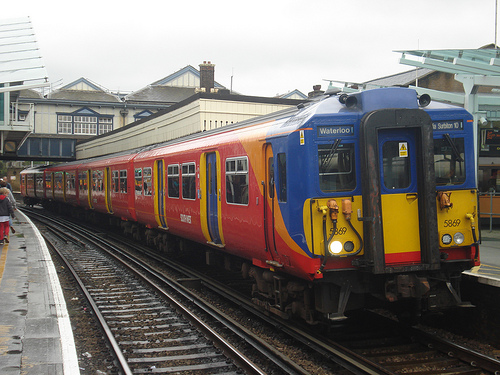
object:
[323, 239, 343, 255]
headlight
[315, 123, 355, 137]
sign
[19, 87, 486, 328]
train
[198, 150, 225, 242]
door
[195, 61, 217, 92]
chimney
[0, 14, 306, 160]
building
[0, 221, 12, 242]
pants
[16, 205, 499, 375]
tracks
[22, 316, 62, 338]
bricks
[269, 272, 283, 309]
ladder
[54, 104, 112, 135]
window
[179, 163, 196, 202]
windows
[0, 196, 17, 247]
people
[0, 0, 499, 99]
sky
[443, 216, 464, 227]
train number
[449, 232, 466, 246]
headlights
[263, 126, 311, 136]
red stripe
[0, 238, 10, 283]
stripe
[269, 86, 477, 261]
blue stripe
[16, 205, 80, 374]
edge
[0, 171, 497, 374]
station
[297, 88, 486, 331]
front